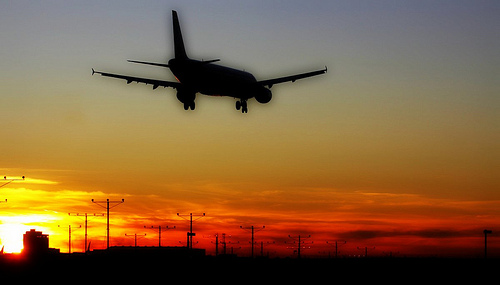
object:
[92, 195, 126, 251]
light pole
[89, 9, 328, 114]
plane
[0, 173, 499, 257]
clouds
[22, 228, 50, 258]
building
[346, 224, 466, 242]
shade in the sky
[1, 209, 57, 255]
sun is setting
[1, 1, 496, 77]
blue sky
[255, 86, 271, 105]
engine under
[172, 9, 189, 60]
tail fin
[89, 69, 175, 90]
left wing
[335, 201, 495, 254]
darkest clouds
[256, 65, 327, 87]
right wing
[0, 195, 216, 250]
sky is red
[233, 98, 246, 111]
wheels of plane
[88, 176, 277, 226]
yellow sky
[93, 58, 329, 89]
set of wings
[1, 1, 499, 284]
an evening scene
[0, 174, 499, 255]
sunset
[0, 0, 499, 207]
sky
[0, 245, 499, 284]
land